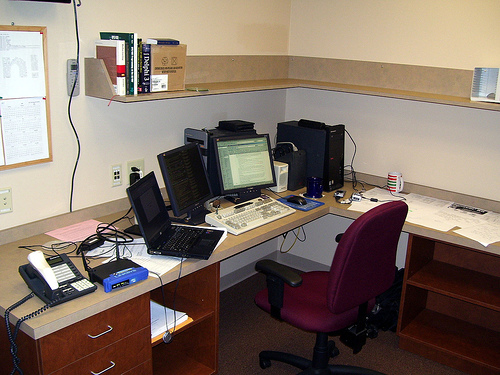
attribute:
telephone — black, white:
[2, 245, 97, 354]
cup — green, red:
[386, 171, 404, 196]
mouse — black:
[284, 192, 307, 206]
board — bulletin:
[0, 21, 55, 171]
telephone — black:
[16, 240, 94, 315]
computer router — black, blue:
[79, 229, 153, 297]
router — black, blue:
[79, 229, 146, 292]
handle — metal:
[85, 324, 116, 343]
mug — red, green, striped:
[385, 168, 405, 195]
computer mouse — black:
[287, 195, 304, 203]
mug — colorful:
[385, 169, 407, 195]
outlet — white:
[128, 159, 144, 179]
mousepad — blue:
[276, 194, 325, 212]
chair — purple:
[244, 203, 434, 372]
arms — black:
[249, 224, 354, 289]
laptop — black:
[120, 167, 223, 266]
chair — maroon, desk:
[266, 202, 411, 370]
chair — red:
[257, 193, 415, 366]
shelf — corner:
[74, 51, 498, 112]